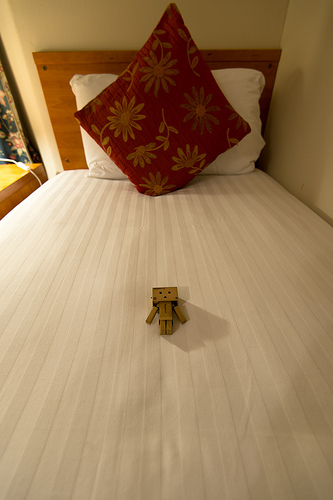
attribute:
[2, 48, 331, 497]
bed — little, wooden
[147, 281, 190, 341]
doll — wooden, cute, brown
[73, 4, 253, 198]
pillow — diamond shaped, red, standing up, burgundy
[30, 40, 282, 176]
head board — brown, wooden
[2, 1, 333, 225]
wall — cream colored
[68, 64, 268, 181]
pillow — white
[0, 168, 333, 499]
bed spread — striped, white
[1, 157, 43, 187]
cord — white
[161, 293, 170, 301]
nose — black